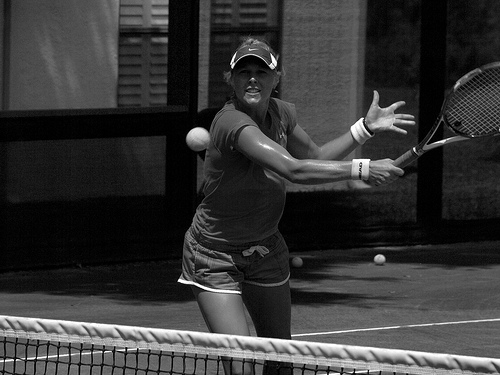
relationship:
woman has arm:
[175, 36, 416, 369] [234, 120, 370, 185]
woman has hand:
[175, 36, 416, 369] [364, 89, 416, 139]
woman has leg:
[175, 36, 416, 369] [188, 285, 254, 373]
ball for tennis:
[187, 126, 211, 154] [8, 9, 493, 369]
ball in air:
[187, 126, 211, 154] [11, 12, 485, 360]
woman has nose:
[175, 36, 416, 369] [245, 75, 259, 86]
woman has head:
[175, 36, 416, 369] [222, 34, 285, 108]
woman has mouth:
[175, 36, 416, 369] [240, 84, 263, 97]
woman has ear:
[175, 36, 416, 369] [272, 68, 282, 93]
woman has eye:
[175, 36, 416, 369] [237, 65, 250, 78]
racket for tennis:
[392, 56, 495, 170] [8, 9, 493, 369]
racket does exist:
[392, 56, 495, 170] [385, 54, 496, 184]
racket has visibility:
[392, 56, 495, 170] [385, 54, 496, 184]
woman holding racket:
[175, 36, 416, 369] [392, 56, 495, 170]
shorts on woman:
[177, 222, 292, 296] [175, 36, 416, 369]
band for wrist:
[350, 156, 371, 182] [350, 158, 371, 182]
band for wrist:
[352, 115, 376, 149] [349, 117, 372, 149]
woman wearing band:
[175, 36, 416, 369] [350, 156, 371, 182]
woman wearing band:
[175, 36, 416, 369] [352, 115, 376, 149]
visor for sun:
[228, 40, 280, 75] [11, 15, 493, 364]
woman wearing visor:
[175, 36, 416, 369] [228, 40, 280, 75]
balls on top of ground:
[292, 256, 304, 268] [6, 243, 494, 369]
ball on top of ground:
[372, 250, 387, 268] [6, 243, 494, 369]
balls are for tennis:
[292, 249, 388, 267] [8, 9, 493, 369]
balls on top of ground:
[292, 249, 388, 267] [6, 243, 494, 369]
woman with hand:
[175, 36, 416, 369] [364, 89, 416, 139]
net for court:
[3, 314, 494, 369] [6, 243, 494, 369]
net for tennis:
[3, 314, 494, 369] [8, 9, 493, 369]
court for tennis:
[6, 243, 494, 369] [8, 9, 493, 369]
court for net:
[6, 243, 494, 369] [3, 314, 494, 369]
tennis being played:
[8, 9, 493, 369] [167, 23, 496, 332]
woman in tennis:
[175, 36, 416, 369] [8, 9, 493, 369]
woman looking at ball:
[175, 36, 416, 369] [187, 126, 211, 154]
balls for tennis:
[292, 256, 304, 268] [8, 9, 493, 369]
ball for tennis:
[372, 250, 387, 268] [8, 9, 493, 369]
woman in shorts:
[175, 36, 416, 369] [177, 222, 292, 296]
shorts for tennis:
[177, 222, 292, 296] [8, 9, 493, 369]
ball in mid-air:
[187, 126, 211, 154] [11, 11, 496, 310]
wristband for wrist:
[350, 156, 371, 182] [350, 158, 371, 182]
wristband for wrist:
[352, 115, 376, 149] [349, 117, 372, 149]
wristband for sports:
[350, 156, 371, 182] [14, 12, 490, 352]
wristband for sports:
[352, 115, 376, 149] [14, 12, 490, 352]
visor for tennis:
[228, 40, 280, 75] [8, 9, 493, 369]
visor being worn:
[228, 40, 280, 75] [222, 34, 285, 108]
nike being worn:
[247, 45, 261, 57] [225, 37, 281, 108]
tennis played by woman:
[8, 9, 493, 369] [175, 36, 416, 369]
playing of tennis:
[167, 23, 496, 332] [8, 9, 493, 369]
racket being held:
[392, 56, 495, 170] [361, 154, 408, 187]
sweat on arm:
[240, 125, 350, 185] [234, 120, 370, 185]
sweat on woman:
[240, 125, 350, 185] [175, 36, 416, 369]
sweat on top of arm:
[240, 125, 350, 185] [234, 120, 370, 185]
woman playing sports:
[175, 36, 416, 369] [14, 12, 490, 352]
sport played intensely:
[8, 9, 493, 369] [200, 37, 416, 195]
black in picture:
[11, 11, 490, 365] [11, 11, 491, 368]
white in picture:
[8, 10, 493, 367] [11, 11, 491, 368]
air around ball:
[11, 12, 485, 360] [187, 126, 211, 154]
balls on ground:
[292, 256, 304, 268] [6, 243, 494, 369]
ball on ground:
[372, 250, 387, 268] [6, 243, 494, 369]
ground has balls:
[6, 243, 494, 369] [292, 249, 388, 267]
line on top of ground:
[7, 311, 496, 366] [6, 243, 494, 369]